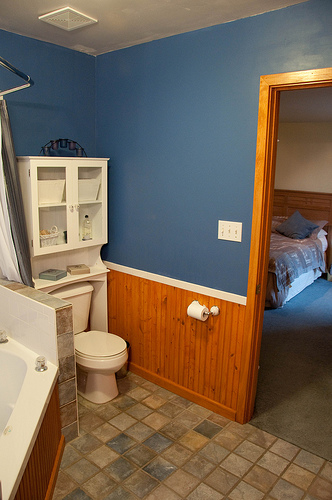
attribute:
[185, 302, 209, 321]
toilet paper — white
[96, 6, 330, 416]
wall — blue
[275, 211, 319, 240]
pillow — blue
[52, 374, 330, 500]
floor — tiled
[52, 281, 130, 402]
toilet — porcelain, white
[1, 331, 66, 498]
bathtub — jacuzzi, white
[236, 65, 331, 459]
doorway — open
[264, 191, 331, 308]
bed — made up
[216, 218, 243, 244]
light switch — white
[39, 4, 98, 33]
ceiling vent — white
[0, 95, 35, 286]
shower curtain — gray, white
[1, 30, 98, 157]
wall — blue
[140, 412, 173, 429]
stone — small, multicolored, mixed matched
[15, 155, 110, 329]
cupboard — big, white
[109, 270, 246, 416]
boarding — orange-brown, wooden, wood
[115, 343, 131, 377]
trash bin — metal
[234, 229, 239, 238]
switch — white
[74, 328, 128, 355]
lid — closed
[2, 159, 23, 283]
screen — white